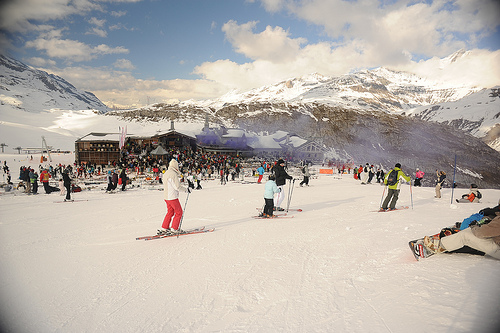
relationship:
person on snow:
[261, 173, 282, 220] [0, 160, 499, 329]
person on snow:
[377, 161, 407, 212] [0, 160, 499, 329]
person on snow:
[158, 152, 196, 225] [10, 196, 478, 330]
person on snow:
[273, 159, 293, 207] [0, 48, 498, 330]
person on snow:
[273, 159, 293, 207] [0, 160, 499, 329]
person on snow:
[158, 152, 196, 225] [0, 160, 499, 329]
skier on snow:
[62, 164, 76, 200] [0, 160, 499, 329]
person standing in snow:
[158, 152, 196, 225] [0, 205, 494, 331]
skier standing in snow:
[62, 164, 76, 200] [0, 160, 499, 329]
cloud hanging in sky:
[220, 19, 308, 66] [122, 11, 228, 56]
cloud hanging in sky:
[206, 19, 217, 32] [122, 11, 228, 56]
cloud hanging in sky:
[177, 57, 182, 67] [122, 11, 228, 56]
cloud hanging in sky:
[111, 57, 141, 72] [122, 11, 228, 56]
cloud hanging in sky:
[81, 24, 110, 40] [122, 11, 228, 56]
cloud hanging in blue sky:
[220, 19, 308, 66] [147, 1, 204, 58]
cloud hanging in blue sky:
[259, 0, 285, 13] [147, 1, 204, 58]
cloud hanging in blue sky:
[287, 2, 390, 46] [147, 1, 204, 58]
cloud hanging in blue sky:
[380, 4, 444, 57] [147, 1, 204, 58]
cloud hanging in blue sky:
[434, 32, 465, 59] [147, 1, 204, 58]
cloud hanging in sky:
[44, 27, 61, 37] [0, 2, 497, 113]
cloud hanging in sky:
[85, 15, 105, 26] [0, 2, 497, 113]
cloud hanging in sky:
[87, 28, 107, 38] [0, 2, 497, 113]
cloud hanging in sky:
[21, 37, 94, 62] [0, 2, 497, 113]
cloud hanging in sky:
[30, 54, 47, 66] [0, 2, 497, 113]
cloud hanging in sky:
[438, 9, 485, 37] [0, 2, 497, 113]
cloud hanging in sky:
[467, 31, 481, 45] [0, 2, 497, 113]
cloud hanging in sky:
[386, 4, 439, 58] [0, 2, 497, 113]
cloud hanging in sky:
[430, 0, 448, 10] [0, 2, 497, 113]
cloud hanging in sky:
[440, 32, 455, 42] [0, 2, 497, 113]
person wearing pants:
[261, 173, 282, 220] [261, 196, 275, 216]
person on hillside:
[158, 152, 196, 225] [138, 188, 228, 259]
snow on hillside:
[267, 223, 402, 290] [6, 156, 497, 331]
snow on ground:
[0, 48, 498, 330] [0, 152, 498, 331]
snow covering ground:
[0, 48, 498, 330] [0, 152, 498, 331]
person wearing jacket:
[158, 152, 196, 225] [139, 165, 226, 222]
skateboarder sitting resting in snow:
[402, 208, 499, 268] [0, 160, 499, 329]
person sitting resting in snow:
[377, 161, 407, 212] [0, 160, 499, 329]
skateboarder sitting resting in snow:
[448, 182, 492, 211] [0, 160, 499, 329]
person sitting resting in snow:
[158, 152, 196, 225] [0, 60, 499, 185]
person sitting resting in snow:
[261, 173, 282, 220] [0, 60, 499, 185]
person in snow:
[158, 152, 196, 225] [0, 160, 499, 329]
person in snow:
[273, 159, 293, 207] [0, 160, 499, 329]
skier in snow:
[413, 167, 424, 185] [0, 160, 499, 329]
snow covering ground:
[0, 160, 499, 329] [0, 152, 498, 331]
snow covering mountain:
[148, 42, 498, 147] [2, 27, 499, 189]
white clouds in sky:
[9, 5, 106, 42] [8, 5, 481, 130]